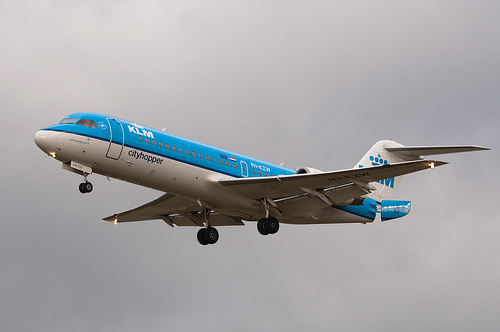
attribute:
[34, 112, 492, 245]
airplane — flying, blue, white, multi colored, large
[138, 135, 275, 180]
windows — small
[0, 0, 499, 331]
sky — dark